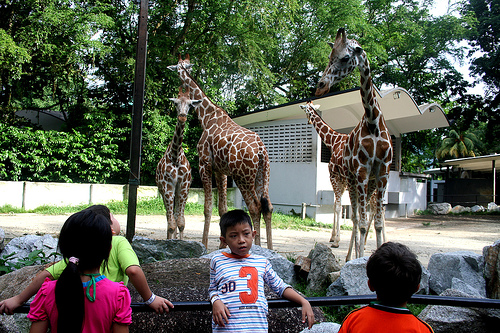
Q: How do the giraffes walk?
A: Legs.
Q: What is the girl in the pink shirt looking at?
A: Giraffes.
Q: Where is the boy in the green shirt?
A: In front of the girl.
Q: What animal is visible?
A: Giraffes.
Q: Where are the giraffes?
A: In the enclosure.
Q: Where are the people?
A: In front of the railing.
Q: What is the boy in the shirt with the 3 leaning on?
A: A railing.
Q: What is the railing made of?
A: Metal.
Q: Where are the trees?
A: Behind the fence.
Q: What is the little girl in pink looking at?
A: The giraffes.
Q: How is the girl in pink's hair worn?
A: In a ponytail.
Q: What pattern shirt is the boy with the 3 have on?
A: Striped.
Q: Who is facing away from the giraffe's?
A: The boy in the striped shirt.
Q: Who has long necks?
A: The giraffe.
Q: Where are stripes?
A: On boy's shirt.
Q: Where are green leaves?
A: On the trees.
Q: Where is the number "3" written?
A: On boy's shirt.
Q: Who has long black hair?
A: Girl in pink shirt.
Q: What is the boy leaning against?
A: A railing.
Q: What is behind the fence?
A: Large gray rocks.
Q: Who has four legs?
A: One giraffe.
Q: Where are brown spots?
A: On the giraffe.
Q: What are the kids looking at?
A: Giraffes.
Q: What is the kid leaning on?
A: Pole.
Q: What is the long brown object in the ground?
A: Post.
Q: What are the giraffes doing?
A: Looking and park visitors and two looking away.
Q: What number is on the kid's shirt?
A: 3.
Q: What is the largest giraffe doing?
A: Turning away.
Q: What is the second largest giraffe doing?
A: Considers park visitors.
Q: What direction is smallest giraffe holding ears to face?
A: Perpendicular.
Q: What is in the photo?
A: Giraffes.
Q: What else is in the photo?
A: Kids.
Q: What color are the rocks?
A: Grey.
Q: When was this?
A: Daytime.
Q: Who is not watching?
A: The kid in a number 3 shirt.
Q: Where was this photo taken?
A: At an enclosure at a zoo.